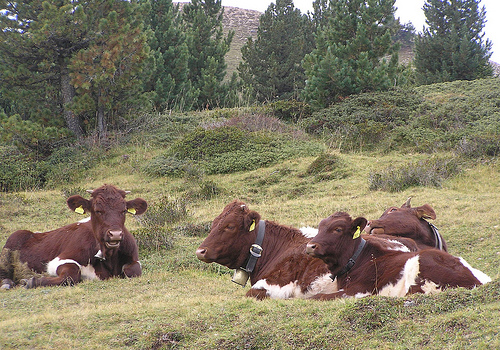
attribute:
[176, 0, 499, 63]
sky — grey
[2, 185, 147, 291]
cow — laying, facing, relaxed, resting, sitting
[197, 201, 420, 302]
cow — laying, brown, big, large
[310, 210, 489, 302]
cow — laying, brown, white, hornless, resting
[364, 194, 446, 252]
cow — laying, one, lying, resting, adult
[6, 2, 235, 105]
trees — full, viewable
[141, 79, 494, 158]
hills — small, grassy, green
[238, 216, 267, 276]
collar — black, belt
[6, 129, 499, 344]
grass — green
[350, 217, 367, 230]
ear — tagged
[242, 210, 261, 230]
ear — tagged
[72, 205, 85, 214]
tag — yellow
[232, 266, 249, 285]
bell — golden, hanging, partial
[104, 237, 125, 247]
mouth — open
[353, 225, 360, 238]
tag — yellow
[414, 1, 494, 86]
trees — pine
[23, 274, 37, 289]
hoof — black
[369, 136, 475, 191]
brush — straw like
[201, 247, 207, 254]
nostril — large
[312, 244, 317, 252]
nostril — large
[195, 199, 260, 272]
head — large